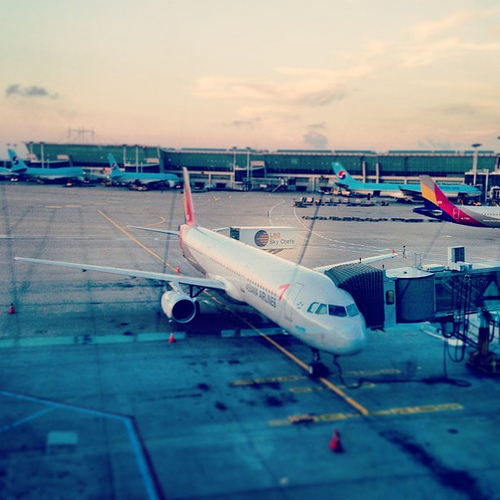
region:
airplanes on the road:
[27, 140, 489, 473]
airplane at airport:
[18, 135, 420, 455]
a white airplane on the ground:
[17, 144, 470, 424]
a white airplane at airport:
[65, 132, 497, 425]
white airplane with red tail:
[55, 135, 443, 422]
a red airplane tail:
[105, 140, 271, 310]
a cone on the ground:
[317, 394, 379, 498]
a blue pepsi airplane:
[314, 126, 485, 220]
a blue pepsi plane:
[320, 145, 485, 218]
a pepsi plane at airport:
[317, 151, 495, 222]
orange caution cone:
[324, 420, 354, 461]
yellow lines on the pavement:
[331, 384, 371, 416]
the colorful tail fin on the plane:
[418, 181, 462, 222]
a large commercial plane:
[127, 173, 375, 356]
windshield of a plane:
[322, 297, 361, 320]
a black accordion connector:
[340, 263, 383, 289]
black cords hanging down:
[454, 286, 471, 361]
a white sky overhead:
[151, 9, 434, 114]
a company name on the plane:
[237, 275, 310, 320]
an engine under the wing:
[154, 288, 216, 320]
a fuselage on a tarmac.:
[158, 194, 395, 372]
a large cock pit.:
[276, 291, 377, 371]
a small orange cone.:
[318, 425, 352, 461]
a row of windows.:
[183, 234, 283, 307]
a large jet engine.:
[139, 272, 205, 344]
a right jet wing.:
[0, 238, 235, 298]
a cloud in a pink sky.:
[0, 70, 96, 155]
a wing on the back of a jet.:
[172, 149, 196, 232]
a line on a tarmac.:
[7, 365, 182, 497]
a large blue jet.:
[323, 153, 490, 217]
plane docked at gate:
[13, 167, 403, 397]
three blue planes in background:
[4, 146, 481, 203]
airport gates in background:
[16, 140, 498, 182]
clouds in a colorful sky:
[1, 0, 498, 149]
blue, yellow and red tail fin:
[410, 172, 486, 227]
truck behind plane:
[227, 225, 300, 252]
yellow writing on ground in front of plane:
[227, 365, 465, 427]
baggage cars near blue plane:
[293, 195, 390, 207]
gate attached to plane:
[323, 257, 498, 334]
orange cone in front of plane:
[329, 427, 344, 457]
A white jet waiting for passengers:
[11, 155, 434, 390]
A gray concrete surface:
[33, 198, 129, 255]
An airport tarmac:
[26, 198, 123, 249]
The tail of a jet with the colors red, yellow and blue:
[406, 169, 479, 234]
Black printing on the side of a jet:
[237, 278, 278, 315]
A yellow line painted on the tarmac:
[79, 203, 143, 246]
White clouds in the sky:
[189, 50, 399, 120]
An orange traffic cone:
[321, 426, 355, 461]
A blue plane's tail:
[319, 150, 364, 195]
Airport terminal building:
[193, 143, 479, 180]